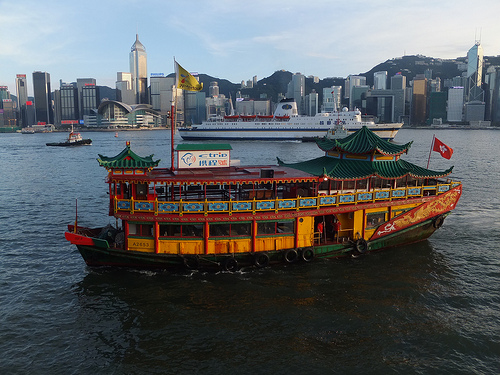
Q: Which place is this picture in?
A: It is at the river.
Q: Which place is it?
A: It is a river.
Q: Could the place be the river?
A: Yes, it is the river.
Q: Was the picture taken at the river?
A: Yes, it was taken in the river.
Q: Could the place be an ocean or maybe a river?
A: It is a river.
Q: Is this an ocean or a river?
A: It is a river.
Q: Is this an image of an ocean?
A: No, the picture is showing a river.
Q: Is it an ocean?
A: No, it is a river.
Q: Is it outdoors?
A: Yes, it is outdoors.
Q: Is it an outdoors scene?
A: Yes, it is outdoors.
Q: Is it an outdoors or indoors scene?
A: It is outdoors.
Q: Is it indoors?
A: No, it is outdoors.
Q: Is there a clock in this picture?
A: No, there are no clocks.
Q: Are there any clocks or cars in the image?
A: No, there are no clocks or cars.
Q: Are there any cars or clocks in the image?
A: No, there are no clocks or cars.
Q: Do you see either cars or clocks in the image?
A: No, there are no clocks or cars.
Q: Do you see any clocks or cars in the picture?
A: No, there are no clocks or cars.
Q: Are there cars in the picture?
A: No, there are no cars.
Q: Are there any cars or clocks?
A: No, there are no cars or clocks.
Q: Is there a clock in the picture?
A: No, there are no clocks.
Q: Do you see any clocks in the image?
A: No, there are no clocks.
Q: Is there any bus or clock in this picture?
A: No, there are no clocks or buses.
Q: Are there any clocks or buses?
A: No, there are no clocks or buses.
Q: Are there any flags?
A: Yes, there is a flag.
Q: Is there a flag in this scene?
A: Yes, there is a flag.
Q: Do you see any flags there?
A: Yes, there is a flag.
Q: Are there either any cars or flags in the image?
A: Yes, there is a flag.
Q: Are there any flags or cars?
A: Yes, there is a flag.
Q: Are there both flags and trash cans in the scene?
A: No, there is a flag but no trash cans.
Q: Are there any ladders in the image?
A: No, there are no ladders.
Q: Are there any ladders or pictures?
A: No, there are no ladders or pictures.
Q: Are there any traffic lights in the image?
A: No, there are no traffic lights.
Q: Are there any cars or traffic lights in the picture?
A: No, there are no traffic lights or cars.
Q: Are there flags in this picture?
A: Yes, there is a flag.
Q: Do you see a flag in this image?
A: Yes, there is a flag.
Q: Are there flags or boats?
A: Yes, there is a flag.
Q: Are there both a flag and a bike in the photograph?
A: No, there is a flag but no bikes.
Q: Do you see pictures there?
A: No, there are no pictures.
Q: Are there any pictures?
A: No, there are no pictures.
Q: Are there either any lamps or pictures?
A: No, there are no pictures or lamps.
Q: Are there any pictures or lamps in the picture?
A: No, there are no pictures or lamps.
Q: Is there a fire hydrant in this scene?
A: No, there are no fire hydrants.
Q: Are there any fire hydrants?
A: No, there are no fire hydrants.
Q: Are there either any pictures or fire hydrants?
A: No, there are no fire hydrants or pictures.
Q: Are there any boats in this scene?
A: Yes, there is a boat.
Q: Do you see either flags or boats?
A: Yes, there is a boat.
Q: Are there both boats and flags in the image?
A: Yes, there are both a boat and a flag.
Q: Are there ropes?
A: No, there are no ropes.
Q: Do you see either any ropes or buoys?
A: No, there are no ropes or buoys.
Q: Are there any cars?
A: No, there are no cars.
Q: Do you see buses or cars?
A: No, there are no cars or buses.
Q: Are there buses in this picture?
A: No, there are no buses.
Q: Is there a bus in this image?
A: No, there are no buses.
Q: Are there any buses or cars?
A: No, there are no buses or cars.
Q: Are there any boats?
A: Yes, there is a boat.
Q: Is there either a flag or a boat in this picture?
A: Yes, there is a boat.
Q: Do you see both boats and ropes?
A: No, there is a boat but no ropes.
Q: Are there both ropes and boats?
A: No, there is a boat but no ropes.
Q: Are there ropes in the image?
A: No, there are no ropes.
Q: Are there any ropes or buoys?
A: No, there are no ropes or buoys.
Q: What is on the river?
A: The boat is on the river.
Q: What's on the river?
A: The boat is on the river.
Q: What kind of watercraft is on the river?
A: The watercraft is a boat.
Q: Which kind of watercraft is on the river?
A: The watercraft is a boat.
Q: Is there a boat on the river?
A: Yes, there is a boat on the river.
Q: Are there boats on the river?
A: Yes, there is a boat on the river.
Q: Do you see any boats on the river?
A: Yes, there is a boat on the river.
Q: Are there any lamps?
A: No, there are no lamps.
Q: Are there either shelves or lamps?
A: No, there are no lamps or shelves.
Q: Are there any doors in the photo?
A: Yes, there is a door.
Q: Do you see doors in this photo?
A: Yes, there is a door.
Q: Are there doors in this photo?
A: Yes, there is a door.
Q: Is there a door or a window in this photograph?
A: Yes, there is a door.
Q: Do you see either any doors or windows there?
A: Yes, there is a door.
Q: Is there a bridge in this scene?
A: No, there are no bridges.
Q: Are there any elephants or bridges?
A: No, there are no bridges or elephants.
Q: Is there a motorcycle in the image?
A: No, there are no motorcycles.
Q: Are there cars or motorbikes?
A: No, there are no motorbikes or cars.